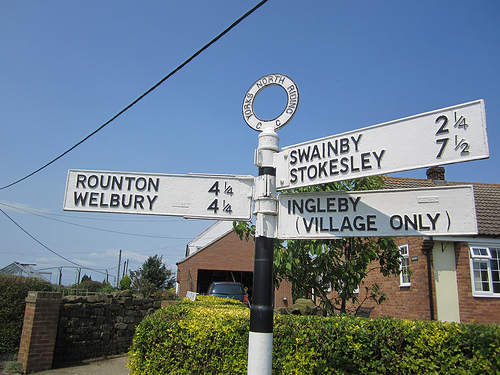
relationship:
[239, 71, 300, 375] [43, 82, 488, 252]
pole with signs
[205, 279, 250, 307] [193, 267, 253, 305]
car parked at door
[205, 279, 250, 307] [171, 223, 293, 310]
car parked at garage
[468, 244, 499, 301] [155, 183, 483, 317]
window on building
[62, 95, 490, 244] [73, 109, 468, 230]
street signs with black lettering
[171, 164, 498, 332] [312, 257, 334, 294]
building with window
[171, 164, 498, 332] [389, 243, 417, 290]
building with window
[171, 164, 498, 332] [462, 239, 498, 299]
building with window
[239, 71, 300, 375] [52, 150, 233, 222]
pole with sign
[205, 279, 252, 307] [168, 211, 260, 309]
car parked in front of building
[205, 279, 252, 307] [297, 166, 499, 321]
car parked in front of building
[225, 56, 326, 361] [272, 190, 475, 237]
pole for sign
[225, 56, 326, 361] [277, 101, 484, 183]
pole for sign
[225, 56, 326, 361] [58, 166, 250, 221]
pole for sign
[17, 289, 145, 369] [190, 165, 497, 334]
retaining wall next to house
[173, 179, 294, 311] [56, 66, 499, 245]
building behind a sign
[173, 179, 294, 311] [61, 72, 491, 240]
building behind signs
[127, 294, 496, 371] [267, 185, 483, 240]
bushes behind sign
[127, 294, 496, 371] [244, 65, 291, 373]
bushes behind pole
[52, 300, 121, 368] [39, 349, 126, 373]
retaining wall beside a driveway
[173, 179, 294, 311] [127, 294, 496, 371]
building behind bushes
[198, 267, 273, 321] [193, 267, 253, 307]
vehicle parked in garage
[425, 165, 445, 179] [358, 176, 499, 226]
chimney built on top of roof